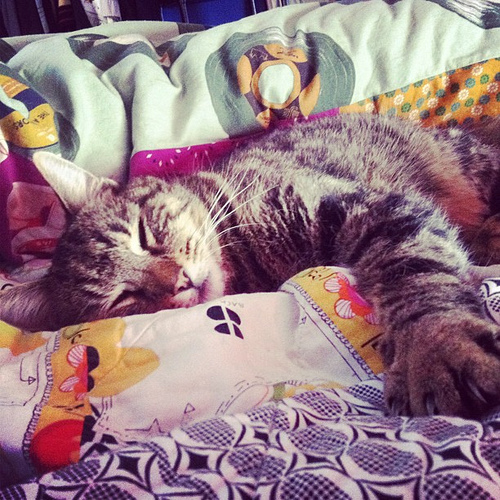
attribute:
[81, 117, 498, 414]
cat — resting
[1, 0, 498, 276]
pillow — grey, red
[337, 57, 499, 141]
stripe — yellow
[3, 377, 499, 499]
pillow — red, grey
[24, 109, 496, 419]
cat — resting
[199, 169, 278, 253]
whiskers — white